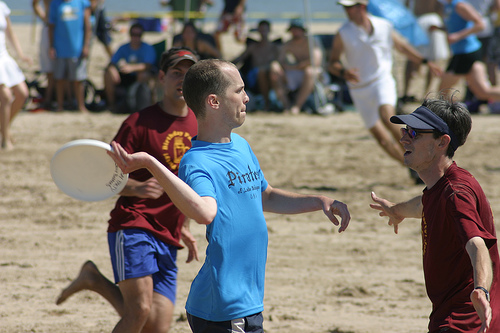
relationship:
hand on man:
[246, 174, 381, 253] [172, 55, 272, 322]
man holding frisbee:
[105, 58, 351, 333] [44, 137, 131, 206]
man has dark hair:
[368, 97, 498, 331] [422, 97, 473, 157]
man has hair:
[105, 58, 351, 333] [178, 55, 236, 117]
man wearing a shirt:
[368, 97, 498, 331] [112, 98, 195, 252]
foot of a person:
[55, 259, 94, 305] [108, 43, 213, 325]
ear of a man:
[203, 87, 223, 116] [105, 58, 351, 333]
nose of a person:
[242, 90, 249, 103] [103, 56, 354, 328]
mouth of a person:
[234, 104, 247, 117] [103, 56, 354, 328]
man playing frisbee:
[105, 58, 351, 333] [50, 138, 129, 202]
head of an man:
[398, 96, 473, 172] [368, 97, 498, 331]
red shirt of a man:
[416, 161, 496, 331] [368, 97, 498, 331]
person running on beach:
[327, 0, 444, 175] [245, 110, 395, 195]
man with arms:
[368, 97, 498, 331] [393, 190, 494, 295]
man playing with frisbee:
[105, 58, 351, 333] [41, 135, 132, 213]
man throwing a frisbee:
[105, 58, 351, 333] [50, 138, 129, 202]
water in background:
[5, 2, 345, 22] [0, 0, 408, 30]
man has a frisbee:
[118, 52, 356, 315] [51, 138, 130, 208]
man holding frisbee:
[105, 58, 351, 333] [48, 139, 124, 201]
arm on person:
[108, 140, 218, 221] [103, 56, 354, 328]